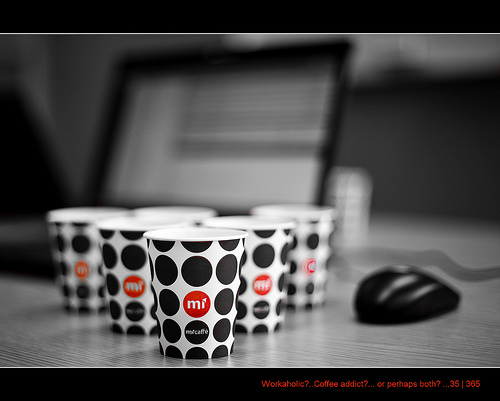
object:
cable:
[332, 237, 499, 285]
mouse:
[349, 250, 466, 328]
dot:
[70, 233, 91, 253]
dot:
[51, 233, 67, 250]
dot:
[56, 259, 70, 277]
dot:
[74, 284, 91, 299]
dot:
[57, 282, 74, 299]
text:
[257, 378, 480, 389]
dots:
[180, 255, 213, 286]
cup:
[136, 206, 215, 225]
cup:
[139, 226, 248, 360]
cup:
[202, 215, 295, 334]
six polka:
[48, 201, 336, 363]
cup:
[246, 202, 338, 314]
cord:
[326, 237, 488, 287]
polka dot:
[177, 254, 213, 287]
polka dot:
[213, 253, 238, 286]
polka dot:
[161, 317, 181, 344]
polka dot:
[212, 316, 229, 342]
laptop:
[2, 37, 356, 284]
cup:
[97, 217, 194, 337]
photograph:
[5, 3, 498, 395]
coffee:
[181, 288, 211, 348]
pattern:
[181, 289, 211, 320]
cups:
[42, 205, 134, 316]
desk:
[0, 202, 498, 369]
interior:
[153, 233, 231, 240]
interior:
[104, 219, 174, 225]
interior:
[260, 206, 324, 216]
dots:
[153, 253, 179, 288]